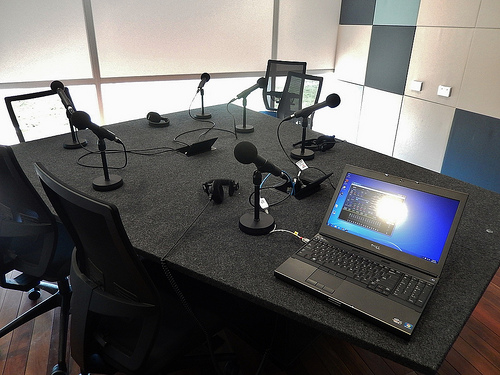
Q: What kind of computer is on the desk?
A: Laptop.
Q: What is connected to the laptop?
A: Microphones.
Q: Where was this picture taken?
A: Studio.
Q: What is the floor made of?
A: Wood.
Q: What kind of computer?
A: Laptop.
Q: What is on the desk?
A: Microphones.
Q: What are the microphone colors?
A: Black.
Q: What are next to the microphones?
A: Headphones.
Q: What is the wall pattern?
A: Tiles.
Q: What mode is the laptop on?
A: Turned on.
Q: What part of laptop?
A: Screen.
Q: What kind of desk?
A: Office desk.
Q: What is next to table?
A: Chair.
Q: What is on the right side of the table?
A: Black laptop.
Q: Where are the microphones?
A: On the table.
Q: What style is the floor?
A: Hardwood.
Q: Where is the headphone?
A: On the table.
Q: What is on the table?
A: Microphones and laptop.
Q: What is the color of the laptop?
A: Black.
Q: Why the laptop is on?
A: To be used.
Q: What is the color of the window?
A: White.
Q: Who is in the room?
A: No one.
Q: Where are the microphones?
A: On the table.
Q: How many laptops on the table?
A: One.